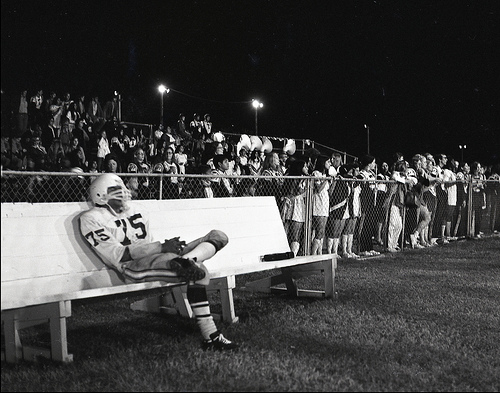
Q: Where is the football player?
A: On the bench.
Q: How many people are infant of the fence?
A: One.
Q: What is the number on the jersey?
A: 75.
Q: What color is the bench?
A: White.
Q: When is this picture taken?
A: At night.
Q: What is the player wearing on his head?
A: Helmet.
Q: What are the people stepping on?
A: Grass.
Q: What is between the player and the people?
A: Fence.